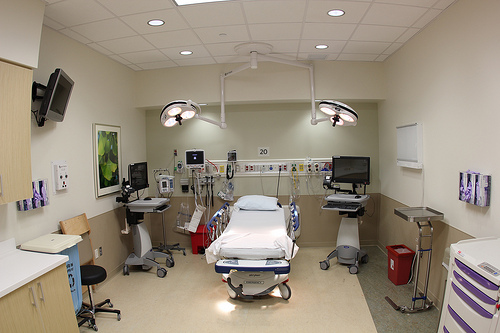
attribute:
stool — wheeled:
[74, 259, 121, 330]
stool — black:
[83, 259, 125, 326]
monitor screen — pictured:
[330, 154, 372, 186]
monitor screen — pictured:
[183, 146, 206, 170]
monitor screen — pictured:
[124, 160, 150, 191]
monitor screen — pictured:
[36, 65, 76, 125]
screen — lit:
[394, 127, 426, 178]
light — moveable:
[317, 97, 361, 131]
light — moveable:
[160, 94, 201, 132]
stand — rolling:
[318, 202, 370, 272]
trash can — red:
[384, 241, 419, 291]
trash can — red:
[187, 219, 219, 258]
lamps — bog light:
[116, 64, 384, 159]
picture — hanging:
[94, 122, 124, 201]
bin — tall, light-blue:
[13, 230, 87, 314]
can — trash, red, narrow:
[359, 220, 458, 308]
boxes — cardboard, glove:
[455, 164, 493, 213]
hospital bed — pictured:
[215, 177, 305, 300]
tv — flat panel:
[44, 65, 76, 123]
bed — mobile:
[197, 189, 297, 269]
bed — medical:
[212, 192, 304, 270]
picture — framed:
[91, 125, 121, 200]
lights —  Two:
[158, 55, 253, 131]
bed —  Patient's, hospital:
[204, 193, 299, 301]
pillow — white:
[233, 193, 282, 212]